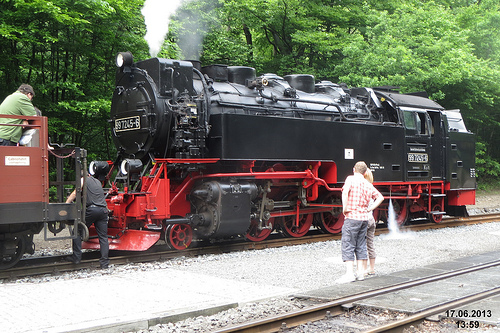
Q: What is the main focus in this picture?
A: A red and black train.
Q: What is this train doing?
A: Stopped on tracks.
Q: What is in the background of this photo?
A: A forest.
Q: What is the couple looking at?
A: The side of a train.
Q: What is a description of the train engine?
A: Black and red.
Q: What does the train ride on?
A: Train tracks.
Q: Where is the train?
A: On the tracks.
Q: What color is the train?
A: Black.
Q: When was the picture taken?
A: Daytime.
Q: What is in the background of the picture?
A: Trees.